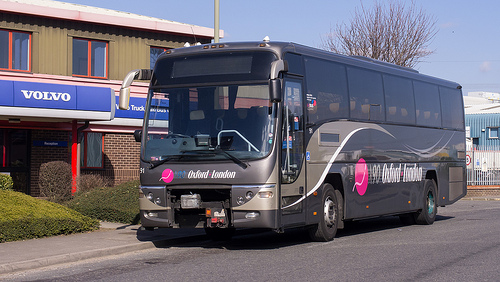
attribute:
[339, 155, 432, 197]
logo — pink, white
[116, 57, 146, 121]
mirror — silver, black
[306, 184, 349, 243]
tire — black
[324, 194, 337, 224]
rim — silver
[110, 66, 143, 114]
mirror — silver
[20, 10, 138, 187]
building — aluminum, brick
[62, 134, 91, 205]
pole — red, metal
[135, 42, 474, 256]
bus — grey, silver, shiny, large, gray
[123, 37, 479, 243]
bus — shiny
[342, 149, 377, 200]
logo — pink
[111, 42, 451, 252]
bus — gray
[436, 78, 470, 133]
window — big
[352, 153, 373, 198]
logo — round, pink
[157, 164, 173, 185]
logo — small, round, pink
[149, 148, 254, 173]
windshield wipers — black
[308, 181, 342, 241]
tire — black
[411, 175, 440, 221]
tire — black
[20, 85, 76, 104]
logo — white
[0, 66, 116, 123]
sign — blue